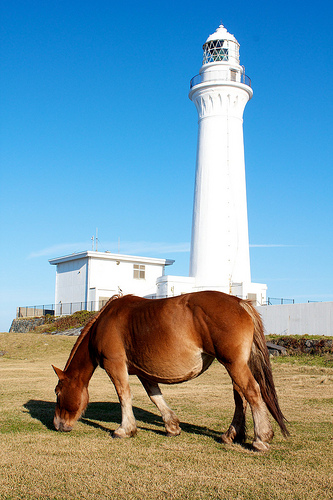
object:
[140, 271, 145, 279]
window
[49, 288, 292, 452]
horse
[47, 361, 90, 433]
head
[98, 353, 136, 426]
leg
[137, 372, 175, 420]
leg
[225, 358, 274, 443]
leg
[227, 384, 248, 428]
leg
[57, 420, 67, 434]
mouth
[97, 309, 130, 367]
fur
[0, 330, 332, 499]
grass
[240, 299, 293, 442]
tail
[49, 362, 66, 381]
ear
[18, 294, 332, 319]
fence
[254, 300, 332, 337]
wall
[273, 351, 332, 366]
vegetation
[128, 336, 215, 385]
belly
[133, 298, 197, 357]
fur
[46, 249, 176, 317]
building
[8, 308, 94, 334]
hill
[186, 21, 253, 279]
light house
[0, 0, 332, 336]
sky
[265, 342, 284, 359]
rocks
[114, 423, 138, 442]
hoof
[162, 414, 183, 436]
hoof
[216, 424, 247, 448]
hoof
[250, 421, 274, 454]
hoof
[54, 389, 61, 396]
horse eye